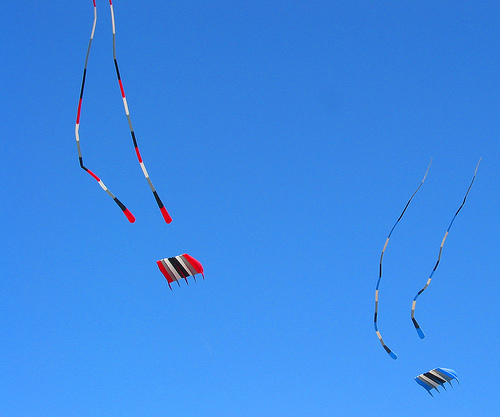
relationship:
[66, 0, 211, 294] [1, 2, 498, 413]
kite in sky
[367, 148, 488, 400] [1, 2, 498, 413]
kite in sky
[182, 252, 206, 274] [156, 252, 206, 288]
stripe on kite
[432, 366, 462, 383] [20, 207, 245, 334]
stripes on kite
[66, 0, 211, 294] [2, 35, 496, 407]
kite in sky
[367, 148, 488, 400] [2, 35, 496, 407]
kite in sky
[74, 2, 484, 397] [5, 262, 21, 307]
kites in sky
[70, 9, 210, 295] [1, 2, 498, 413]
kite in sky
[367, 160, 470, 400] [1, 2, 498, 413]
kite in sky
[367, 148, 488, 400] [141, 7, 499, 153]
kite in sky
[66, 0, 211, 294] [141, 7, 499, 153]
kite in sky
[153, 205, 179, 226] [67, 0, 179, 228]
red stripe on tail of kite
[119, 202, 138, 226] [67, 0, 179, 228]
red stripe on tail of kite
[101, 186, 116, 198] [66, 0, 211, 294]
gray stripe on kite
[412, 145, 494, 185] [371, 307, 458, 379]
tips of kite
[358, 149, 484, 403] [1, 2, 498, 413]
kites flying in sky